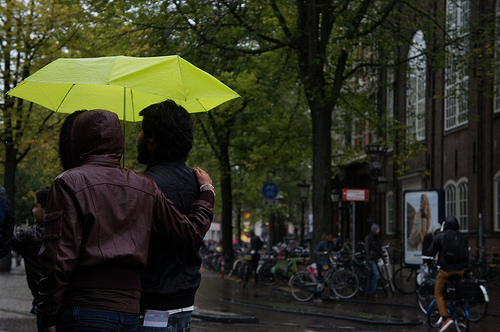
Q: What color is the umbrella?
A: Green.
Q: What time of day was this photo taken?
A: Day time.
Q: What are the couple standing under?
A: An umbrella.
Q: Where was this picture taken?
A: In a city.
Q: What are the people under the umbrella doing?
A: Walking.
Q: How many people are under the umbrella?
A: Two.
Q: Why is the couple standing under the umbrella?
A: Because it is raining.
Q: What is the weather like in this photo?
A: It is raining.